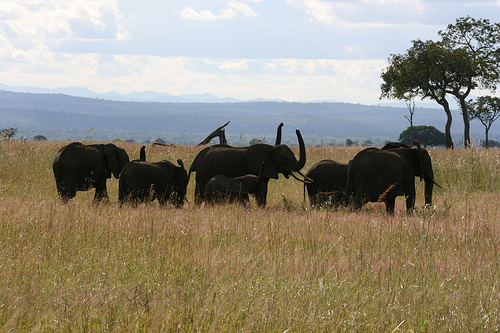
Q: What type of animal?
A: Elephants.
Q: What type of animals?
A: Elephant.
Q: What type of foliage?
A: Grass.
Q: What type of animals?
A: Elephants.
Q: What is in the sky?
A: Clouds.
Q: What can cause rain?
A: Clouds.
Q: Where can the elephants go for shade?
A: Under the trees.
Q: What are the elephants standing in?
A: Grassy plains.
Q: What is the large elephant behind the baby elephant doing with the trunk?
A: Holding it up.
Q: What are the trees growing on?
A: Grassy plains.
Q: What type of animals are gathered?
A: Elephants.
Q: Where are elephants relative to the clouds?
A: Below the clouds.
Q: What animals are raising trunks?
A: Elephants.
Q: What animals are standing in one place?
A: Elephants.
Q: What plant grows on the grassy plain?
A: Grass.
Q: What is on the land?
A: Gray elephant on plain.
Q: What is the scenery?
A: Group of elephants in a field.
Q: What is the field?
A: A field of grass.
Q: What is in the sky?
A: White clouds in the sky.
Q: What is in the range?
A: View of mountain range far ahead.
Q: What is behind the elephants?
A: Group of trees behind the elephants.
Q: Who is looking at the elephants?
A: The photographer.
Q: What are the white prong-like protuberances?
A: Tusks.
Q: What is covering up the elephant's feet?
A: The grass.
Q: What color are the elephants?
A: Grey.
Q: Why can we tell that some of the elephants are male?
A: They have tusks.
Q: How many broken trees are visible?
A: One.